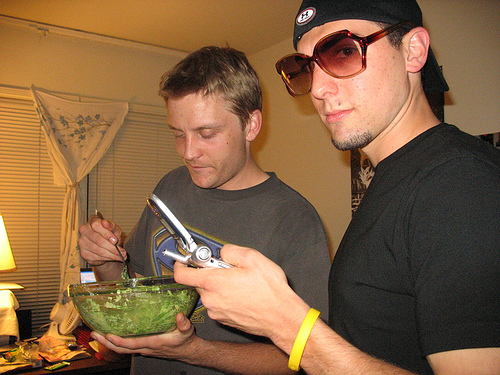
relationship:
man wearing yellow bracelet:
[272, 3, 498, 373] [288, 306, 324, 373]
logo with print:
[279, 14, 336, 35] [298, 10, 309, 20]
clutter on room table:
[11, 341, 66, 361] [0, 332, 125, 374]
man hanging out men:
[272, 3, 498, 373] [77, 38, 326, 371]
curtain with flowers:
[30, 85, 131, 332] [31, 103, 113, 157]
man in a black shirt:
[272, 3, 498, 373] [327, 124, 499, 364]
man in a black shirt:
[73, 41, 330, 371] [327, 124, 499, 364]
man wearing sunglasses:
[272, 3, 498, 373] [273, 31, 373, 99]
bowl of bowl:
[60, 275, 214, 338] [60, 275, 214, 338]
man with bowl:
[73, 41, 330, 371] [60, 275, 214, 338]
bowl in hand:
[60, 275, 214, 338] [90, 304, 195, 358]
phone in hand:
[143, 191, 235, 290] [173, 242, 289, 342]